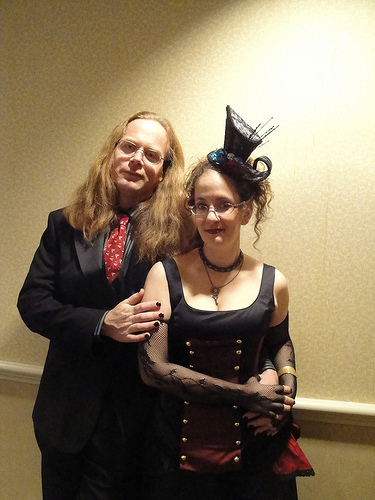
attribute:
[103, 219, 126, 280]
tie — red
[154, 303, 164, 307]
nails — black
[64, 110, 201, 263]
hair — blonde, long, curly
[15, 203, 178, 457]
jacket — black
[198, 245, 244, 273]
choker — black, chain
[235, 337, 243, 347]
button — brass, gold, yellow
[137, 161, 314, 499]
woman — blonde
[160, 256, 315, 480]
top — black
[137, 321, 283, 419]
gloves — fishnet, black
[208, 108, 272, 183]
hat — black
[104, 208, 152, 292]
shirt — grey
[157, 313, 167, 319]
fingernails — black